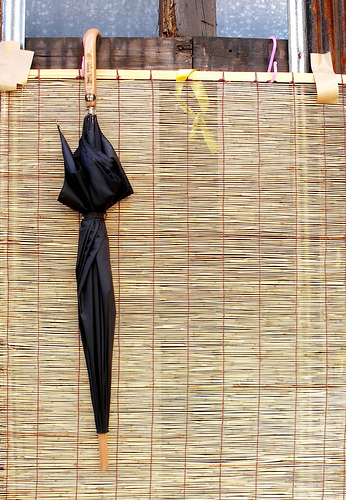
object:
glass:
[25, 0, 288, 39]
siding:
[0, 0, 28, 51]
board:
[25, 35, 293, 78]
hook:
[80, 35, 89, 79]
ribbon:
[173, 68, 221, 154]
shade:
[1, 67, 345, 499]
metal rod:
[89, 106, 95, 115]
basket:
[0, 68, 346, 500]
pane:
[25, 0, 158, 38]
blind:
[1, 67, 337, 495]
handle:
[82, 27, 102, 107]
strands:
[116, 282, 327, 463]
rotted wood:
[158, 0, 182, 36]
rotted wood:
[24, 36, 288, 73]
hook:
[267, 35, 278, 83]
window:
[25, 0, 288, 37]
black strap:
[82, 209, 107, 221]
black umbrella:
[55, 26, 134, 472]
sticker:
[85, 93, 96, 102]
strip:
[310, 51, 339, 105]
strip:
[2, 49, 34, 92]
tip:
[98, 431, 108, 470]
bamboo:
[0, 61, 346, 500]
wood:
[193, 37, 268, 72]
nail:
[229, 49, 233, 53]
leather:
[62, 169, 116, 219]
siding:
[287, 0, 308, 72]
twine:
[148, 84, 155, 499]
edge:
[233, 35, 249, 39]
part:
[233, 8, 246, 24]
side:
[246, 14, 254, 22]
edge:
[212, 353, 223, 368]